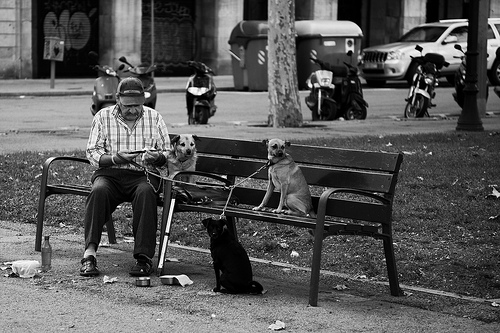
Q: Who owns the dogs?
A: Elderly man.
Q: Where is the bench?
A: City park.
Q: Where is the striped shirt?
A: On the elderly man.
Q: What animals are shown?
A: Dogs.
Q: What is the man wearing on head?
A: Hat.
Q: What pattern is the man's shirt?
A: Plaid.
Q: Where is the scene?
A: Roadside on the street.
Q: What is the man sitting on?
A: Bench.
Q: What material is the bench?
A: Wood.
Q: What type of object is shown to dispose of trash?
A: Litter bin.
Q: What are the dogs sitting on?
A: Bench.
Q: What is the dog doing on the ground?
A: Sitting.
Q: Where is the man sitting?
A: On a bench.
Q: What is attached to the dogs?
A: A rope leash.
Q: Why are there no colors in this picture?
A: Black and white.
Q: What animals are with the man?
A: Dogs.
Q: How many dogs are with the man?
A: 3.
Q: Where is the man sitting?
A: Bench.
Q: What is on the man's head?
A: Hat.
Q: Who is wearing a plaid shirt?
A: Man.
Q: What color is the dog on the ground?
A: Black.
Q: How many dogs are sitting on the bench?
A: 2.